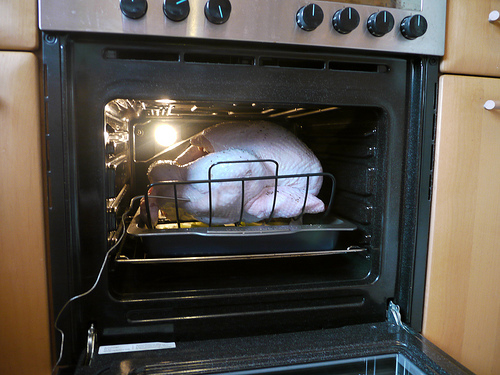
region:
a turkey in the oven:
[141, 111, 333, 227]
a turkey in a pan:
[124, 114, 353, 249]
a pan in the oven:
[124, 197, 362, 257]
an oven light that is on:
[149, 119, 182, 148]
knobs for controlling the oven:
[120, 0, 233, 22]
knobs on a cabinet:
[482, 98, 498, 115]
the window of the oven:
[244, 349, 414, 374]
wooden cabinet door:
[424, 76, 498, 372]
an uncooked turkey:
[142, 117, 350, 221]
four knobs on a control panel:
[294, 0, 427, 40]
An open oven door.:
[61, 78, 475, 371]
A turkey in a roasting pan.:
[72, 78, 423, 281]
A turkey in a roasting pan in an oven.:
[97, 87, 390, 293]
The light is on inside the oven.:
[89, 81, 219, 163]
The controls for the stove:
[100, 0, 439, 46]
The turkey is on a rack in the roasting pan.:
[102, 88, 373, 235]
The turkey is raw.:
[101, 87, 369, 250]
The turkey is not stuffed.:
[73, 76, 392, 263]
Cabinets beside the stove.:
[395, 0, 495, 356]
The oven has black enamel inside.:
[61, 47, 442, 365]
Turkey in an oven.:
[134, 122, 339, 213]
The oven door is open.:
[144, 316, 402, 373]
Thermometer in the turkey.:
[131, 181, 208, 216]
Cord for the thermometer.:
[55, 225, 123, 369]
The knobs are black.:
[94, 0, 471, 45]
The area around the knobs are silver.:
[43, 1, 113, 31]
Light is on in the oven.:
[134, 110, 193, 151]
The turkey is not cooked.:
[181, 127, 307, 209]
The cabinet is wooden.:
[446, 180, 498, 327]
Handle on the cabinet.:
[468, 86, 498, 124]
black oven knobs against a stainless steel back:
[286, 3, 431, 43]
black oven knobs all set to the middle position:
[286, 0, 438, 47]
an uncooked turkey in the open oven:
[128, 111, 342, 231]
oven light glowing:
[116, 103, 244, 225]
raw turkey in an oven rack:
[123, 106, 348, 241]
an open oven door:
[42, 36, 418, 373]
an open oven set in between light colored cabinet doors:
[6, 1, 499, 352]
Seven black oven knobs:
[86, 1, 445, 49]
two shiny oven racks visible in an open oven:
[101, 226, 386, 290]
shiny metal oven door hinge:
[362, 301, 419, 342]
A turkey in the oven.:
[138, 113, 343, 228]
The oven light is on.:
[135, 107, 175, 155]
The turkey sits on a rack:
[154, 166, 354, 238]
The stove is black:
[73, 181, 387, 338]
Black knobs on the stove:
[283, 3, 443, 46]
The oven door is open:
[196, 323, 401, 374]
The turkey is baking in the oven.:
[166, 143, 350, 219]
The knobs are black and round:
[293, 11, 459, 45]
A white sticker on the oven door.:
[98, 338, 179, 355]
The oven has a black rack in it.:
[129, 190, 351, 284]